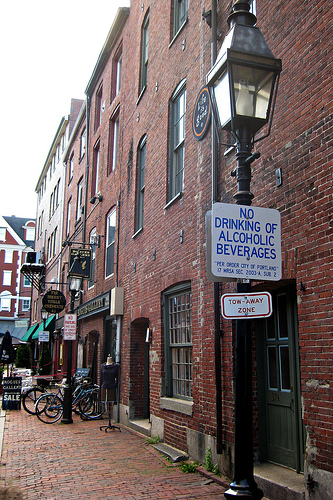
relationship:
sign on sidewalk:
[2, 377, 21, 410] [0, 377, 274, 499]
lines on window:
[120, 460, 168, 479] [160, 284, 195, 403]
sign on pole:
[59, 308, 81, 348] [61, 284, 77, 427]